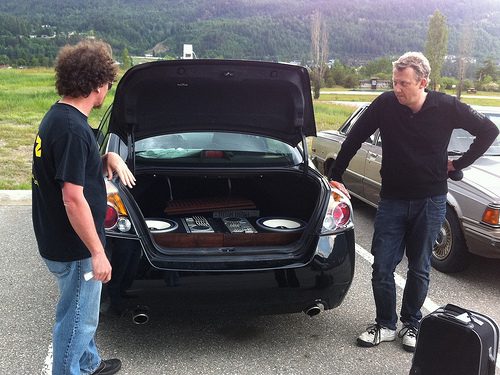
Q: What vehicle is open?
A: The black car.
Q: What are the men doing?
A: Looking in the trunk.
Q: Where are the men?
A: By the trunk.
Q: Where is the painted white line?
A: On the ground.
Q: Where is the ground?
A: Below the men.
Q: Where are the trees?
A: Behind the field.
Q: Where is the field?
A: Behind the car.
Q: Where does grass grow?
A: In the field.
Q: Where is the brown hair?
A: On the left man.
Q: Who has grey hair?
A: The right man.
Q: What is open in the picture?
A: A trunk of a car.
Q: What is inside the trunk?
A: A speaker system.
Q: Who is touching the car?
A: The man in the long-sleeved shirt.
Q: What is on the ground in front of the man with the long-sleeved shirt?
A: Luggage.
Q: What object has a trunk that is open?
A: A car.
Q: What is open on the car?
A: The trunk.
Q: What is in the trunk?
A: A speaker system.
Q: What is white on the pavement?
A: Parking lines.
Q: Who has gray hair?
A: The man leaning on the car.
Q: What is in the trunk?
A: Speakers.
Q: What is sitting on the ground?
A: A suitcase.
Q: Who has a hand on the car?
A: The man with short hair.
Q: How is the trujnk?
A: Open.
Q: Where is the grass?
A: In front of the car.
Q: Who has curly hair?
A: The younger man.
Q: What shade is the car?
A: Black.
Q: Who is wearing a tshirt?
A: The younger man.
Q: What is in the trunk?
A: A car audio system.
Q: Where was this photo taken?
A: Outside.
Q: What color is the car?
A: Black.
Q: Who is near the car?
A: 2 men.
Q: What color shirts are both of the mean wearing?
A: Black.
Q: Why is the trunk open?
A: To show the system.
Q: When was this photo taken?
A: During the day.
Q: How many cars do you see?
A: 2.